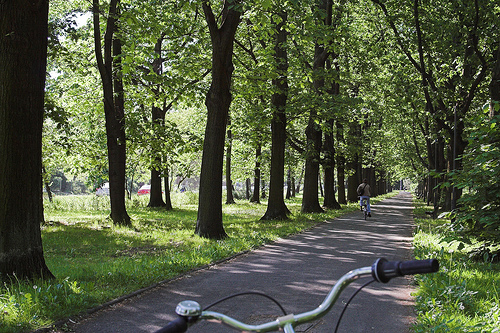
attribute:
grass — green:
[97, 226, 167, 279]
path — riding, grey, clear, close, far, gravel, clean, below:
[308, 203, 415, 263]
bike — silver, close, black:
[238, 252, 418, 324]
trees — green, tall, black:
[185, 5, 315, 236]